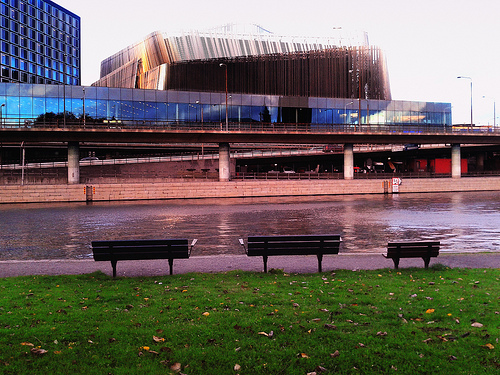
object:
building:
[0, 0, 81, 85]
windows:
[37, 30, 44, 43]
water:
[0, 190, 498, 261]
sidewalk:
[1, 251, 499, 279]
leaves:
[315, 303, 332, 317]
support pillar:
[66, 137, 81, 184]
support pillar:
[218, 143, 229, 182]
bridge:
[0, 121, 500, 185]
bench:
[91, 238, 197, 279]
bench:
[383, 240, 441, 270]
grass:
[0, 269, 500, 375]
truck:
[405, 158, 468, 176]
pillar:
[451, 143, 462, 178]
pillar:
[343, 144, 354, 180]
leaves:
[146, 330, 170, 347]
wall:
[1, 177, 500, 204]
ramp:
[0, 144, 496, 173]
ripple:
[417, 231, 455, 238]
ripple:
[199, 240, 235, 247]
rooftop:
[0, 74, 454, 109]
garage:
[235, 146, 497, 177]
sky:
[53, 0, 497, 123]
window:
[85, 98, 97, 117]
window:
[108, 99, 121, 117]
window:
[189, 103, 201, 121]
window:
[297, 107, 308, 122]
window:
[394, 110, 402, 123]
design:
[90, 21, 391, 101]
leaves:
[423, 327, 455, 346]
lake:
[3, 190, 500, 259]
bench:
[238, 233, 344, 273]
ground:
[0, 250, 500, 375]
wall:
[0, 83, 452, 132]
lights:
[455, 74, 476, 127]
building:
[90, 23, 393, 101]